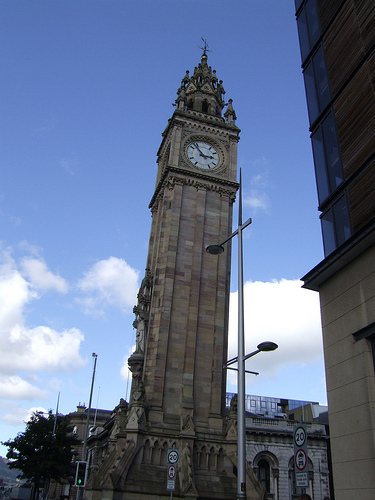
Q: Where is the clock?
A: On the tower.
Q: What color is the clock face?
A: White.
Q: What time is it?
A: 2:53.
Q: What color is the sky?
A: Blue.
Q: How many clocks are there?
A: 1.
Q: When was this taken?
A: Daytime.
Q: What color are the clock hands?
A: Black.